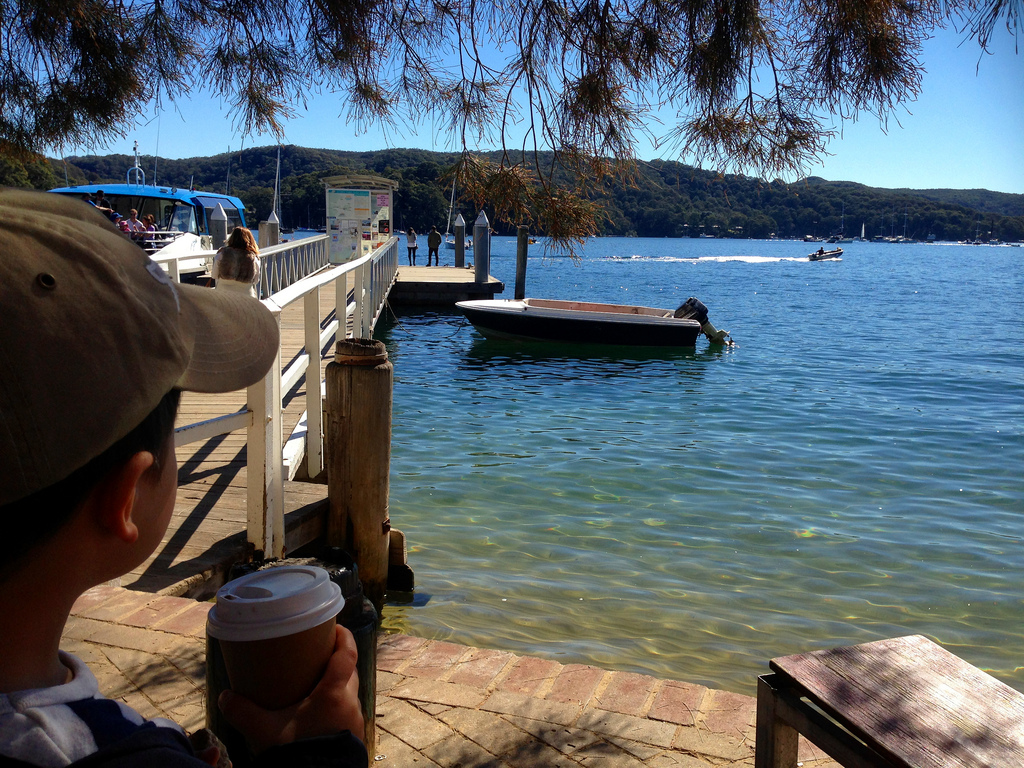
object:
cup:
[203, 557, 350, 759]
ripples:
[785, 380, 920, 458]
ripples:
[851, 284, 961, 374]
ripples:
[480, 427, 538, 472]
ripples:
[625, 359, 794, 424]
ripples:
[473, 364, 626, 446]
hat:
[0, 189, 284, 497]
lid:
[203, 562, 350, 645]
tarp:
[49, 184, 251, 232]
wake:
[586, 249, 800, 268]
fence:
[162, 227, 401, 566]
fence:
[162, 243, 313, 301]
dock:
[135, 265, 385, 598]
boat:
[455, 297, 702, 349]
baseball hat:
[0, 186, 280, 505]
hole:
[36, 272, 60, 292]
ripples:
[451, 351, 894, 622]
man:
[0, 188, 380, 766]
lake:
[569, 402, 930, 575]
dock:
[287, 175, 530, 443]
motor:
[662, 295, 744, 351]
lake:
[367, 224, 1022, 699]